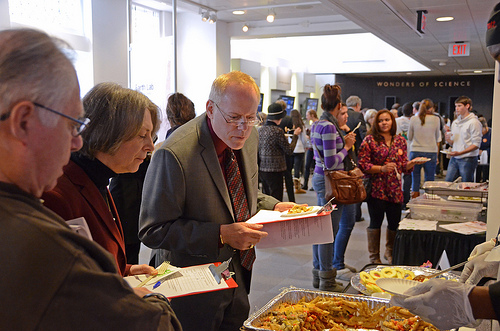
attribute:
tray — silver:
[237, 280, 390, 329]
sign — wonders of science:
[369, 77, 475, 92]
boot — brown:
[382, 222, 394, 264]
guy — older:
[133, 76, 298, 326]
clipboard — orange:
[127, 254, 240, 298]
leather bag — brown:
[326, 163, 371, 205]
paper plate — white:
[375, 276, 425, 298]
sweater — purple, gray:
[307, 112, 346, 185]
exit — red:
[443, 38, 474, 66]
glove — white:
[391, 263, 482, 329]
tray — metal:
[245, 285, 435, 330]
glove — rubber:
[397, 273, 478, 330]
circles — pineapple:
[349, 260, 387, 293]